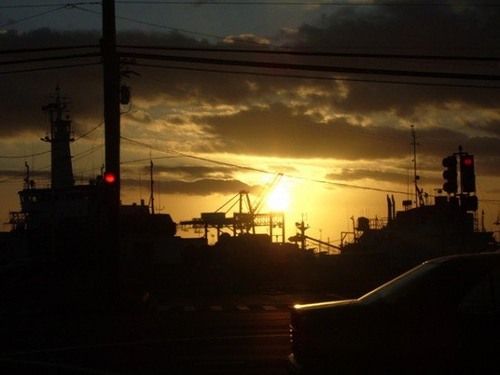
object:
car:
[288, 253, 500, 375]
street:
[25, 281, 286, 372]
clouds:
[323, 166, 445, 186]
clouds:
[121, 178, 251, 197]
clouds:
[325, 65, 405, 114]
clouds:
[0, 26, 105, 141]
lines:
[262, 305, 278, 312]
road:
[216, 296, 292, 374]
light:
[459, 154, 476, 193]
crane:
[236, 172, 285, 229]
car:
[180, 206, 288, 270]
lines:
[116, 45, 498, 63]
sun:
[261, 188, 293, 213]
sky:
[0, 59, 500, 246]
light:
[442, 156, 458, 194]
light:
[103, 172, 116, 184]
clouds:
[187, 100, 317, 159]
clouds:
[466, 133, 499, 158]